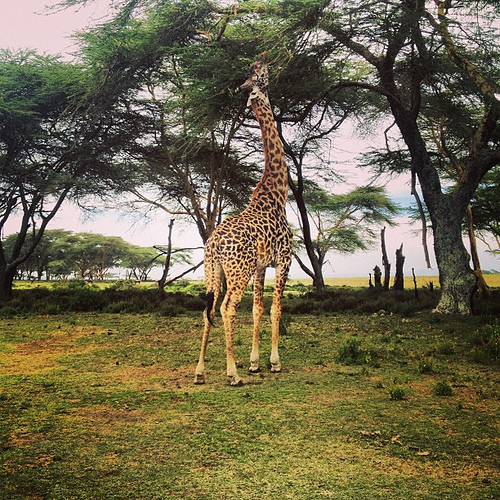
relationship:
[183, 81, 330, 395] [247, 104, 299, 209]
giraffe has neck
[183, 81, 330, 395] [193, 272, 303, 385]
giraffe has legs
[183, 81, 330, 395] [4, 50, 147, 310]
giraffe under tree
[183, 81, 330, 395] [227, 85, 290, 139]
giraffe has head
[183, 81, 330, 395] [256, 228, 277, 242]
giraffe has spot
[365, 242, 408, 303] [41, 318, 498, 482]
stump on ground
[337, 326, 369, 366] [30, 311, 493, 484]
weeds in grass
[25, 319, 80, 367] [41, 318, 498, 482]
dirt on ground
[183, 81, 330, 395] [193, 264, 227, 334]
giraffe has tail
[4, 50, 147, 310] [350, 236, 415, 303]
tree has trunks